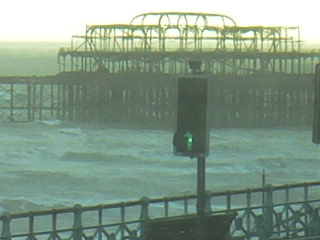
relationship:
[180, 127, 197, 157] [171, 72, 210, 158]
arrow on traffic signal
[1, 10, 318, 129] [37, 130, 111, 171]
bridge over water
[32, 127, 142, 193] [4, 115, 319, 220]
waves in ocean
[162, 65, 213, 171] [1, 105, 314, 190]
light near water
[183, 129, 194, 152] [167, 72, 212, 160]
arrow in light